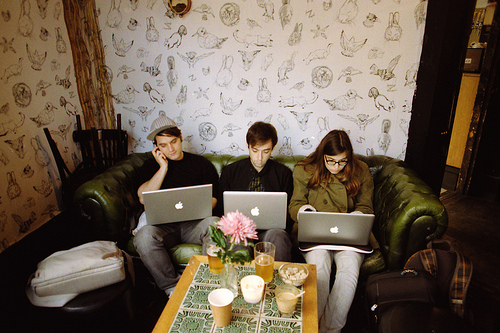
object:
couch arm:
[380, 164, 448, 237]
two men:
[135, 111, 290, 246]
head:
[319, 130, 354, 175]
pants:
[300, 238, 361, 331]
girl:
[294, 127, 371, 332]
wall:
[100, 0, 421, 154]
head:
[143, 115, 185, 162]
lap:
[295, 212, 371, 247]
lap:
[140, 181, 216, 225]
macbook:
[142, 181, 215, 225]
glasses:
[325, 154, 346, 167]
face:
[322, 149, 347, 175]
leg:
[337, 250, 362, 324]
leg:
[307, 247, 333, 324]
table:
[150, 246, 319, 332]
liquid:
[254, 260, 275, 276]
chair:
[43, 113, 125, 192]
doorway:
[424, 0, 499, 196]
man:
[220, 118, 295, 253]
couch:
[67, 155, 447, 273]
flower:
[213, 209, 260, 244]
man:
[132, 109, 225, 289]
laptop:
[220, 188, 289, 229]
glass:
[253, 241, 276, 281]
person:
[286, 124, 380, 305]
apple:
[329, 226, 343, 234]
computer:
[295, 208, 376, 244]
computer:
[220, 189, 290, 228]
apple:
[249, 207, 261, 217]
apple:
[173, 201, 186, 211]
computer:
[140, 182, 215, 225]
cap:
[144, 115, 177, 140]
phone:
[153, 146, 167, 159]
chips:
[293, 269, 299, 271]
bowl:
[276, 263, 309, 283]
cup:
[205, 283, 233, 328]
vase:
[219, 270, 236, 288]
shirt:
[132, 151, 219, 185]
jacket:
[288, 159, 376, 224]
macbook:
[295, 212, 376, 247]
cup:
[205, 285, 240, 326]